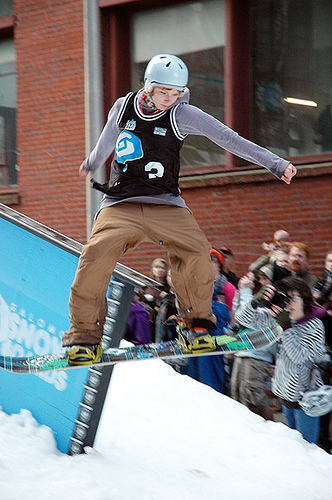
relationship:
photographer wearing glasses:
[233, 277, 331, 444] [290, 289, 303, 300]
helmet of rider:
[142, 52, 193, 94] [60, 53, 298, 369]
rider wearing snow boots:
[60, 53, 298, 369] [59, 323, 227, 354]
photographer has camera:
[230, 277, 331, 443] [267, 290, 290, 308]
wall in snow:
[0, 204, 160, 458] [2, 336, 329, 499]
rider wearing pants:
[60, 53, 298, 369] [61, 201, 218, 344]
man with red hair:
[280, 239, 324, 301] [285, 241, 310, 271]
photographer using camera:
[233, 277, 331, 444] [270, 289, 289, 307]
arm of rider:
[185, 106, 279, 171] [60, 53, 298, 369]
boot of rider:
[61, 329, 114, 367] [60, 53, 298, 369]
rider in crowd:
[60, 53, 298, 369] [143, 229, 330, 445]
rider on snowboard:
[60, 53, 298, 369] [0, 322, 283, 374]